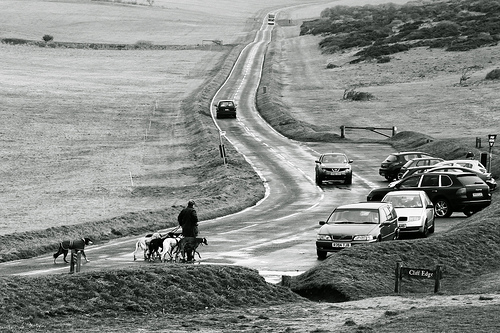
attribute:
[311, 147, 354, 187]
car — parked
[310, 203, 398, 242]
car — parked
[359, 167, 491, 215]
car — parked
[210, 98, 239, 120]
car — parked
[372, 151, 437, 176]
car — parked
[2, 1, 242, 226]
grass — trimmed